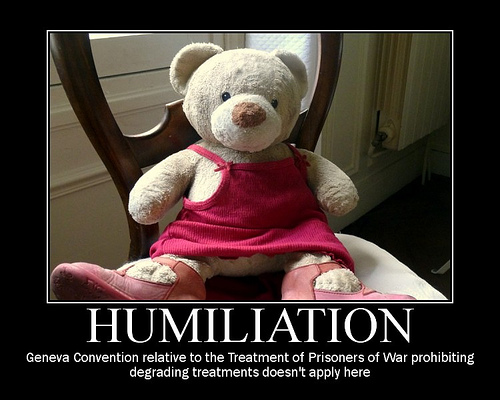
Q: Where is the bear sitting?
A: On a chair.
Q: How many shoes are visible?
A: Two.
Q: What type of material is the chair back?
A: Wood.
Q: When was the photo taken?
A: During the daytime.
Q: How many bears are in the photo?
A: One.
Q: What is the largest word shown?
A: Humiliation.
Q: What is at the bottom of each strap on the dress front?
A: Ribbons.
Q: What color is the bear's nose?
A: Brown.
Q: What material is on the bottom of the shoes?
A: Rubber.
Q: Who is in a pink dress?
A: Teddy bear.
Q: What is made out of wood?
A: A chair.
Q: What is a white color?
A: Letters.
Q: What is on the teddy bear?
A: A dress.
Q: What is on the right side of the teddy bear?
A: Wall radiator.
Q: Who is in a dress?
A: A bear.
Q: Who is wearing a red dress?
A: Teddy bear.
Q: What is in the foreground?
A: A stuffed animal.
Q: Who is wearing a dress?
A: Teddy bear.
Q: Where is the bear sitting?
A: Chair.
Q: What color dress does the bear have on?
A: Pink.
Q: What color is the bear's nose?
A: Brown.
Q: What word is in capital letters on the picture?
A: HUMILIATION.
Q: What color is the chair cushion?
A: White.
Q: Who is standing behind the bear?
A: No one.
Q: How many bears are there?
A: One.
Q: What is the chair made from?
A: Wood.